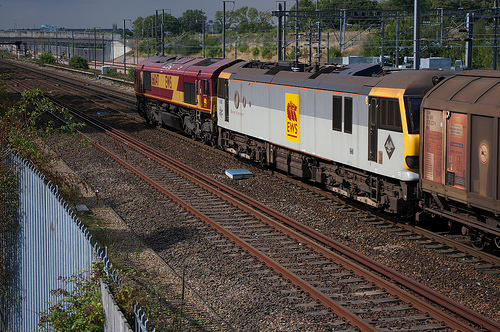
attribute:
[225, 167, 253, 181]
box — silver, blue, white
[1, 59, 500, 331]
tracks — rusted, metal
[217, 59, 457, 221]
train car — gray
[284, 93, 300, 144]
sign — yellow, red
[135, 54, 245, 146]
train car — red, yellow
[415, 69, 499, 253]
train car — rusty, old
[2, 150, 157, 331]
fence — blue, iron, grey, metal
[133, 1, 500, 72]
trees — green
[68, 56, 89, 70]
bush — wild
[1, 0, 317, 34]
sky — blue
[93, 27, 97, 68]
post — metal